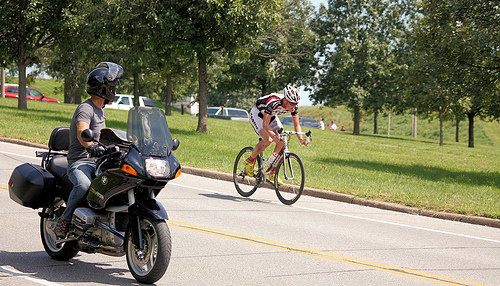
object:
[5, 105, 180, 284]
motorcycle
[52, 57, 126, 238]
man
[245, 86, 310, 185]
person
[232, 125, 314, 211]
bike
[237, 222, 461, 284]
road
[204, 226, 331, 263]
line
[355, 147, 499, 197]
grass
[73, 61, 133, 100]
helmet